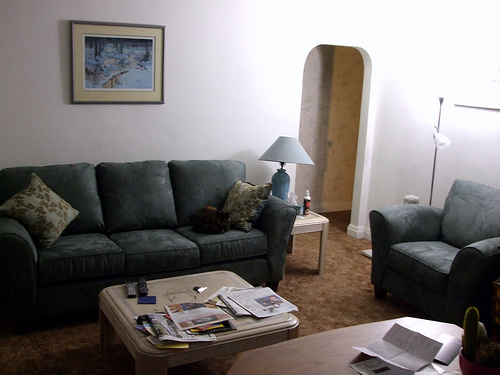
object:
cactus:
[462, 307, 487, 361]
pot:
[459, 349, 500, 375]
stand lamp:
[429, 97, 451, 206]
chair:
[369, 179, 499, 321]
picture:
[70, 20, 166, 105]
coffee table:
[97, 270, 299, 374]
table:
[291, 208, 330, 276]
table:
[218, 315, 478, 373]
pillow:
[0, 173, 79, 250]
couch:
[0, 160, 297, 327]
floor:
[0, 210, 410, 375]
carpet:
[276, 210, 406, 345]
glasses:
[166, 288, 197, 301]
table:
[98, 267, 299, 372]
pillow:
[221, 179, 273, 233]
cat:
[191, 205, 232, 235]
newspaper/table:
[133, 285, 298, 349]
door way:
[295, 45, 363, 234]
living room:
[0, 0, 500, 375]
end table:
[281, 211, 330, 281]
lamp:
[430, 125, 452, 149]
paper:
[351, 323, 443, 374]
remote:
[138, 278, 149, 296]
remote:
[125, 280, 137, 298]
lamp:
[258, 135, 315, 202]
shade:
[258, 135, 316, 166]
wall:
[0, 0, 500, 242]